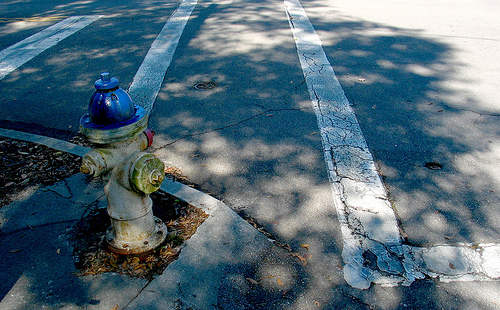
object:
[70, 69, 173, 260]
hydrant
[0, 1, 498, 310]
street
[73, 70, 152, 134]
cap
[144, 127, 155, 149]
plug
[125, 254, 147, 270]
leaves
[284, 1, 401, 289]
line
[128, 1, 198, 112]
line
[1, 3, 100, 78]
line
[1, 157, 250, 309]
sidewalk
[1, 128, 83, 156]
burb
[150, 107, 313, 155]
crack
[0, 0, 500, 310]
shadow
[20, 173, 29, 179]
rock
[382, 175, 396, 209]
weeds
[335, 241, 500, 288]
line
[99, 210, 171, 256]
base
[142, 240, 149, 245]
bolt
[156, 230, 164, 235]
bolt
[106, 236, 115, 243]
bolt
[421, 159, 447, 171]
hole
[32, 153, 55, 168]
leaves